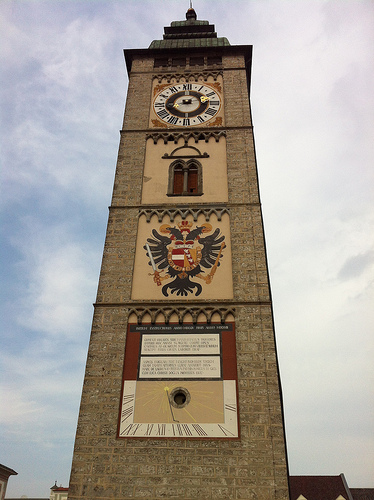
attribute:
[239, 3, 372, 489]
cloud — heavy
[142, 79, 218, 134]
clock — large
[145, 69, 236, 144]
clock — circle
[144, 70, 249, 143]
clock — circular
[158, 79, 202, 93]
numbers — black, inscribed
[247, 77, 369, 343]
clouds — thick, white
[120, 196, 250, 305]
mural — intricate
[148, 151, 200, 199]
windows — small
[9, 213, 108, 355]
cloud — wispy, white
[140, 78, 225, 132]
clock face — white, black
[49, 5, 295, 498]
tower — brown, brick, large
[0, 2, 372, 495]
sky — blue, white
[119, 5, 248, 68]
building top — green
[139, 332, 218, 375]
words — written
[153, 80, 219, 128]
clock — black, white, gold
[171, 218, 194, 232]
crown — drawn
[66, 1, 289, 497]
monument — tall, narrow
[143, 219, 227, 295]
shield — drawn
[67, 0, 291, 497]
clock tower — tan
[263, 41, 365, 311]
clouds — white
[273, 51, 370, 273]
clouds — white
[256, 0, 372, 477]
clouds — white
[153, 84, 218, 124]
face — white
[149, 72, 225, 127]
trim — brown